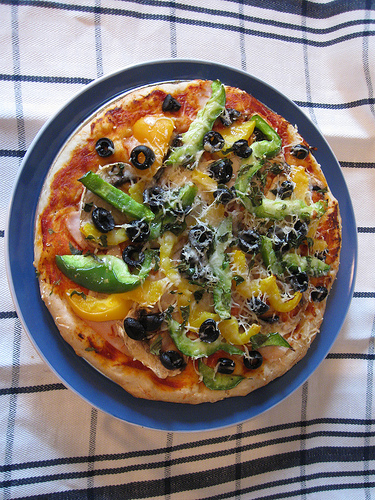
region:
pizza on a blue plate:
[6, 55, 357, 432]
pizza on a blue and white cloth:
[1, 0, 372, 497]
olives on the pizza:
[210, 156, 233, 203]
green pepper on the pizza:
[54, 254, 138, 292]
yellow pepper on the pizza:
[259, 275, 303, 313]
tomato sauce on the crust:
[81, 336, 172, 399]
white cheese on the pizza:
[278, 280, 291, 300]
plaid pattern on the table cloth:
[1, 414, 373, 498]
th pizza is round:
[32, 79, 340, 404]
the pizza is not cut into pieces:
[33, 79, 343, 404]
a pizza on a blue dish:
[4, 52, 369, 438]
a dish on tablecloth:
[7, 3, 371, 498]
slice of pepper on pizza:
[52, 236, 137, 296]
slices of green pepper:
[77, 169, 193, 233]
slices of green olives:
[86, 135, 252, 181]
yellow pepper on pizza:
[68, 289, 137, 324]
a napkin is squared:
[0, 0, 369, 495]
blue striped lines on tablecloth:
[0, 1, 369, 491]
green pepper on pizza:
[246, 134, 279, 205]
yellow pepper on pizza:
[121, 111, 181, 156]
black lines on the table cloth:
[239, 12, 320, 41]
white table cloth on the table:
[37, 37, 108, 57]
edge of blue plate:
[101, 403, 170, 439]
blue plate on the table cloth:
[67, 403, 277, 444]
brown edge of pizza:
[64, 131, 88, 146]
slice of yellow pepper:
[58, 287, 146, 321]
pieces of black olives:
[112, 307, 186, 361]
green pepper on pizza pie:
[77, 166, 150, 221]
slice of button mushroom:
[60, 159, 160, 236]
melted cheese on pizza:
[156, 190, 242, 253]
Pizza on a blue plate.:
[9, 52, 366, 437]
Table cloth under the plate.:
[32, 411, 340, 499]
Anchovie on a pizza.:
[129, 136, 159, 172]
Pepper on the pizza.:
[265, 277, 306, 325]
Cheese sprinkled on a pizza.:
[148, 187, 191, 221]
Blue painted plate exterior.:
[121, 395, 252, 433]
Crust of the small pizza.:
[112, 348, 171, 399]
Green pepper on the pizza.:
[60, 247, 153, 297]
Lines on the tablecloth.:
[254, 441, 357, 493]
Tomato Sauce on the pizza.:
[62, 162, 74, 229]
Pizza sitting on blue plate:
[5, 58, 358, 434]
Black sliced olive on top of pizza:
[218, 358, 234, 373]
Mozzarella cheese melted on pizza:
[179, 226, 214, 279]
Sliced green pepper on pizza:
[81, 169, 154, 225]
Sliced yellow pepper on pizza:
[236, 274, 302, 312]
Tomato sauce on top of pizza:
[44, 169, 79, 289]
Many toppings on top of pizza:
[34, 79, 339, 404]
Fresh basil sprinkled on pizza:
[67, 288, 85, 300]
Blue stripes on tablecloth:
[302, 420, 373, 494]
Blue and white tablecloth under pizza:
[2, 2, 374, 498]